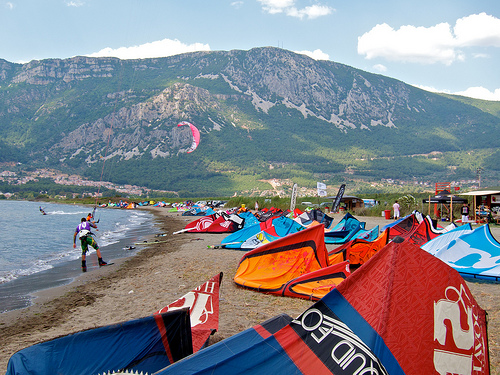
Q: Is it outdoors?
A: Yes, it is outdoors.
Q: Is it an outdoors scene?
A: Yes, it is outdoors.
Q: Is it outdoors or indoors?
A: It is outdoors.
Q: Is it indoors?
A: No, it is outdoors.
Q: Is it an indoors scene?
A: No, it is outdoors.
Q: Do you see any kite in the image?
A: Yes, there is a kite.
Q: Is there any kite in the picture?
A: Yes, there is a kite.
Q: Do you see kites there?
A: Yes, there is a kite.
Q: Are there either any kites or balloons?
A: Yes, there is a kite.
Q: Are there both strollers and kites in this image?
A: No, there is a kite but no strollers.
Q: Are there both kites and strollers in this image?
A: No, there is a kite but no strollers.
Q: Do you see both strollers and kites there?
A: No, there is a kite but no strollers.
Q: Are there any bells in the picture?
A: No, there are no bells.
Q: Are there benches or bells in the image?
A: No, there are no bells or benches.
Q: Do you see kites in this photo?
A: Yes, there is a kite.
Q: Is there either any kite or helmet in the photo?
A: Yes, there is a kite.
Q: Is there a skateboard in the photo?
A: No, there are no skateboards.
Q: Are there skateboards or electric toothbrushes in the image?
A: No, there are no skateboards or electric toothbrushes.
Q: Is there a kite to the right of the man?
A: Yes, there is a kite to the right of the man.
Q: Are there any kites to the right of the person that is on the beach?
A: Yes, there is a kite to the right of the man.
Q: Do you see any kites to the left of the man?
A: No, the kite is to the right of the man.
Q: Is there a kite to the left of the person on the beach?
A: No, the kite is to the right of the man.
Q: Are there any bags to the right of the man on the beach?
A: No, there is a kite to the right of the man.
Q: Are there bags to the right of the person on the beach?
A: No, there is a kite to the right of the man.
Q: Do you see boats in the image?
A: No, there are no boats.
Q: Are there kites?
A: Yes, there is a kite.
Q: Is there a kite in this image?
A: Yes, there is a kite.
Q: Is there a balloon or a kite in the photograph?
A: Yes, there is a kite.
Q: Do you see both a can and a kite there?
A: No, there is a kite but no cans.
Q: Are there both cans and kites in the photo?
A: No, there is a kite but no cans.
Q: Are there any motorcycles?
A: No, there are no motorcycles.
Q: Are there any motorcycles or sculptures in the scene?
A: No, there are no motorcycles or sculptures.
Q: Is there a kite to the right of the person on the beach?
A: Yes, there is a kite to the right of the man.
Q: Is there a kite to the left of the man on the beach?
A: No, the kite is to the right of the man.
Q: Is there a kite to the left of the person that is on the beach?
A: No, the kite is to the right of the man.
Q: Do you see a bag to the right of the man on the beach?
A: No, there is a kite to the right of the man.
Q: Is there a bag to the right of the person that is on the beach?
A: No, there is a kite to the right of the man.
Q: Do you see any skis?
A: No, there are no skis.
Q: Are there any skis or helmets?
A: No, there are no skis or helmets.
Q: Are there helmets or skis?
A: No, there are no skis or helmets.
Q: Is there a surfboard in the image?
A: No, there are no surfboards.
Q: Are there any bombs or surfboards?
A: No, there are no surfboards or bombs.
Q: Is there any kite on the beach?
A: Yes, there are kites on the beach.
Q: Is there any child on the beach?
A: No, there are kites on the beach.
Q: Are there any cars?
A: No, there are no cars.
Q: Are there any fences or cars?
A: No, there are no cars or fences.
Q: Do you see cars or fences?
A: No, there are no cars or fences.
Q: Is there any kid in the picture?
A: No, there are no children.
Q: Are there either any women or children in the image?
A: No, there are no children or women.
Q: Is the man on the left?
A: Yes, the man is on the left of the image.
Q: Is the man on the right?
A: No, the man is on the left of the image.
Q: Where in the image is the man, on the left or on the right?
A: The man is on the left of the image.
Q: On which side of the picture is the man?
A: The man is on the left of the image.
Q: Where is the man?
A: The man is on the beach.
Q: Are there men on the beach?
A: Yes, there is a man on the beach.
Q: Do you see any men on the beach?
A: Yes, there is a man on the beach.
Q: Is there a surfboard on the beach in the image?
A: No, there is a man on the beach.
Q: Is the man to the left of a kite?
A: Yes, the man is to the left of a kite.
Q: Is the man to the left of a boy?
A: No, the man is to the left of a kite.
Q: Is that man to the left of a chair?
A: No, the man is to the left of the kite.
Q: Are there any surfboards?
A: No, there are no surfboards.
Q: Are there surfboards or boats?
A: No, there are no surfboards or boats.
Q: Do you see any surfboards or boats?
A: No, there are no surfboards or boats.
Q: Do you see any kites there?
A: Yes, there is a kite.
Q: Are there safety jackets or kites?
A: Yes, there is a kite.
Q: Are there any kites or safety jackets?
A: Yes, there is a kite.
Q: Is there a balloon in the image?
A: No, there are no balloons.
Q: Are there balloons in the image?
A: No, there are no balloons.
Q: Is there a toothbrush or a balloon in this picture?
A: No, there are no balloons or toothbrushes.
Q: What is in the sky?
A: The kite is in the sky.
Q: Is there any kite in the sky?
A: Yes, there is a kite in the sky.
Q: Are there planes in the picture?
A: No, there are no planes.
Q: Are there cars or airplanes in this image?
A: No, there are no airplanes or cars.